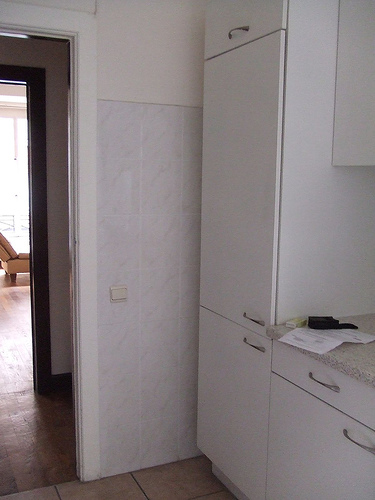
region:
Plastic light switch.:
[95, 276, 137, 319]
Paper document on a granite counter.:
[275, 326, 373, 358]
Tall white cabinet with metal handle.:
[184, 36, 284, 342]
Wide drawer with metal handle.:
[270, 339, 373, 429]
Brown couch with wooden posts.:
[0, 223, 35, 287]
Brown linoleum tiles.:
[6, 479, 212, 498]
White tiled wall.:
[101, 99, 208, 465]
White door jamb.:
[1, 3, 109, 489]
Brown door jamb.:
[0, 47, 62, 437]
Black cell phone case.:
[307, 312, 355, 335]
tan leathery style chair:
[0, 240, 27, 299]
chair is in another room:
[10, 217, 93, 357]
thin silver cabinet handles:
[233, 304, 373, 451]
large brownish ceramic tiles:
[111, 470, 227, 498]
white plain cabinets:
[235, 144, 341, 498]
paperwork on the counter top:
[277, 325, 373, 359]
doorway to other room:
[22, 1, 107, 363]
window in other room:
[0, 109, 33, 226]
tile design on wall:
[78, 121, 203, 440]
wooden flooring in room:
[6, 293, 32, 384]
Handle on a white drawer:
[303, 368, 342, 393]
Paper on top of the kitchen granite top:
[274, 323, 374, 361]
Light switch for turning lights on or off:
[108, 281, 138, 308]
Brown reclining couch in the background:
[0, 231, 46, 284]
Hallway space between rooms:
[0, 379, 95, 485]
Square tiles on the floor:
[2, 452, 259, 499]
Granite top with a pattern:
[260, 310, 373, 385]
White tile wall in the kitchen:
[97, 101, 205, 483]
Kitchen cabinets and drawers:
[188, 0, 374, 496]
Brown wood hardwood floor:
[0, 272, 95, 493]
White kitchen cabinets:
[59, 154, 362, 463]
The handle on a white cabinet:
[232, 332, 269, 364]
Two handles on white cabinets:
[217, 286, 269, 371]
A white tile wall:
[96, 257, 186, 466]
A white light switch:
[96, 267, 144, 329]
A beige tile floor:
[71, 436, 162, 498]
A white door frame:
[50, 294, 119, 499]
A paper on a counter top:
[269, 303, 373, 372]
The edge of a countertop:
[334, 349, 369, 386]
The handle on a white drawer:
[292, 363, 354, 407]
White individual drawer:
[268, 334, 374, 417]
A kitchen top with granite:
[265, 293, 374, 387]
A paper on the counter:
[280, 328, 373, 362]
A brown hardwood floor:
[0, 266, 91, 490]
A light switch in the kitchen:
[109, 285, 130, 311]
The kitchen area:
[88, 6, 369, 494]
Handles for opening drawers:
[235, 303, 267, 354]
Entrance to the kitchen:
[0, 33, 81, 480]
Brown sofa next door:
[0, 235, 40, 281]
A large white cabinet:
[186, 24, 282, 340]